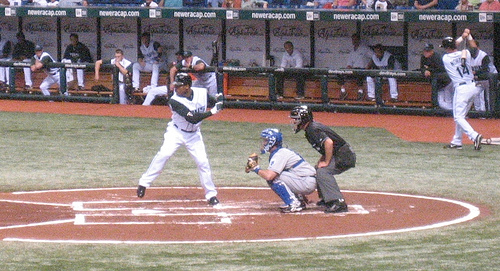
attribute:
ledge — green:
[12, 8, 492, 40]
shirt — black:
[299, 120, 345, 158]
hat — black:
[171, 68, 194, 88]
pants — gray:
[315, 148, 355, 202]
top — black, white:
[164, 88, 213, 122]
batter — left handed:
[135, 72, 222, 206]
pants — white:
[134, 120, 218, 202]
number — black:
[453, 62, 473, 76]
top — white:
[441, 49, 491, 84]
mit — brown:
[242, 141, 279, 211]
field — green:
[13, 72, 474, 267]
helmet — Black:
[281, 100, 331, 140]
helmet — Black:
[156, 32, 222, 102]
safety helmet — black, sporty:
[171, 69, 191, 86]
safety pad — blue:
[270, 179, 291, 208]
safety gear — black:
[286, 102, 312, 135]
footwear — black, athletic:
[207, 194, 219, 206]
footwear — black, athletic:
[135, 185, 147, 200]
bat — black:
[211, 39, 222, 98]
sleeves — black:
[168, 93, 220, 123]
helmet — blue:
[259, 127, 280, 153]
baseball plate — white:
[128, 205, 167, 219]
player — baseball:
[138, 74, 225, 204]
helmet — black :
[170, 72, 191, 86]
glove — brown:
[245, 154, 261, 174]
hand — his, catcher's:
[250, 159, 257, 168]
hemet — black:
[291, 106, 315, 135]